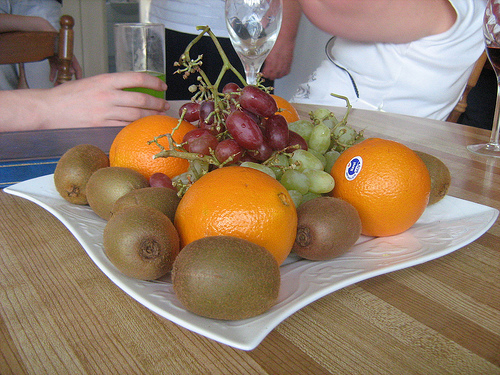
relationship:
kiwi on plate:
[53, 146, 453, 324] [5, 133, 499, 354]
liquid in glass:
[120, 70, 167, 99] [226, 0, 286, 102]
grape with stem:
[169, 79, 308, 177] [172, 22, 245, 91]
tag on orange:
[345, 154, 365, 184] [115, 85, 431, 275]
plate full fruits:
[5, 133, 499, 354] [54, 31, 472, 311]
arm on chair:
[5, 15, 168, 139] [6, 10, 82, 91]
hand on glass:
[9, 69, 170, 128] [116, 20, 176, 116]